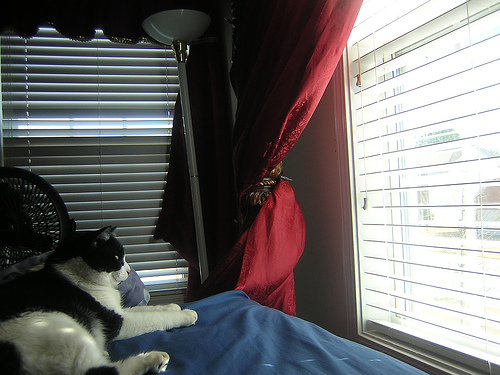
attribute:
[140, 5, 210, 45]
lamp shade — glass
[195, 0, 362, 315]
bed post — red, clothed, twisted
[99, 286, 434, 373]
sheet — blue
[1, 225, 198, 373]
cat — black, white, lying down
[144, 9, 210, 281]
lamp — white, standing, long, tall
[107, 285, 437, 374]
sheets — blue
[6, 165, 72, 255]
fan — off, gray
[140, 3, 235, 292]
lamp — floor